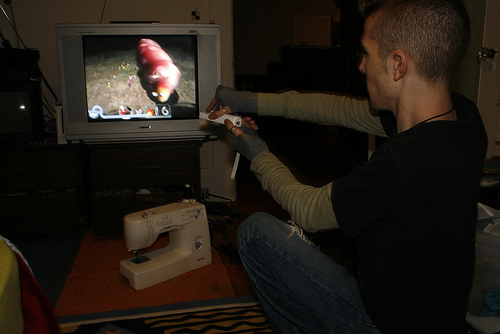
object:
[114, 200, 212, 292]
machine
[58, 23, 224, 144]
tv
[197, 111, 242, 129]
control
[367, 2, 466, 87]
haircut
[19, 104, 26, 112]
knob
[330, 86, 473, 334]
shirt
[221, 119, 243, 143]
thumb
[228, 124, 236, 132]
ring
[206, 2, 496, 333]
man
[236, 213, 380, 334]
jeans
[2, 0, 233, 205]
wall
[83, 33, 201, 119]
game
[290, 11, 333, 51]
computer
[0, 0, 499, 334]
background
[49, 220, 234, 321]
rug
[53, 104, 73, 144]
console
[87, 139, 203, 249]
stand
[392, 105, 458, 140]
necklace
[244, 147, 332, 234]
sleeves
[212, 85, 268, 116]
gloves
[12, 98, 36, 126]
light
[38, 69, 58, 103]
cords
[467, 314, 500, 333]
rag